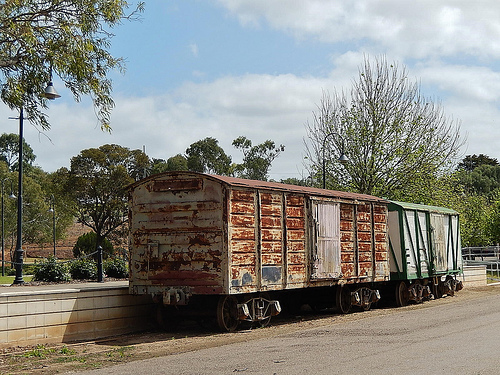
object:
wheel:
[215, 292, 246, 333]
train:
[123, 172, 467, 333]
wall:
[1, 291, 154, 349]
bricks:
[43, 312, 64, 326]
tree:
[50, 143, 150, 277]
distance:
[149, 34, 227, 75]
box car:
[124, 172, 393, 334]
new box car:
[385, 198, 465, 307]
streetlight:
[10, 32, 62, 292]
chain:
[281, 328, 421, 338]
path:
[464, 309, 492, 335]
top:
[80, 143, 132, 163]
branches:
[431, 123, 464, 174]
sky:
[0, 0, 500, 176]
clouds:
[177, 73, 301, 115]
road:
[5, 290, 500, 374]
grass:
[0, 274, 33, 284]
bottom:
[5, 333, 111, 347]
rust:
[231, 189, 256, 265]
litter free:
[395, 341, 500, 375]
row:
[67, 134, 286, 174]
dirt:
[232, 351, 283, 375]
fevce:
[26, 236, 73, 258]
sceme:
[1, 3, 496, 272]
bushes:
[37, 252, 128, 281]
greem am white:
[402, 209, 462, 274]